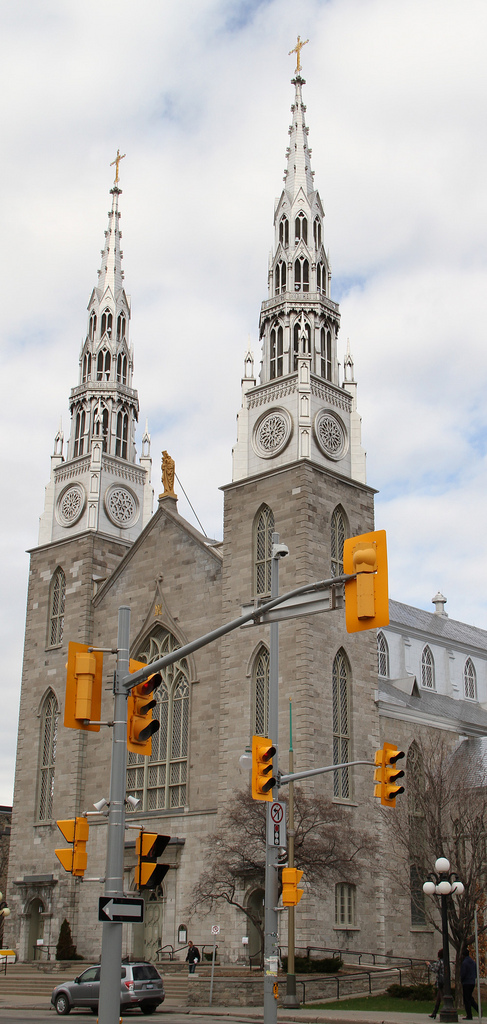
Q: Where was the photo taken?
A: Street in front of church.